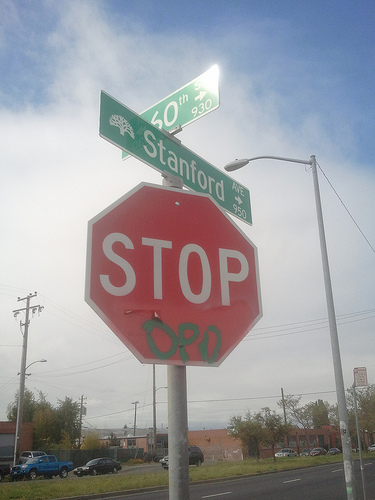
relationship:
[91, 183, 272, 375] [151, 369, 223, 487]
stop sign on pole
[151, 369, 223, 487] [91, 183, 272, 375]
pole holding stop sign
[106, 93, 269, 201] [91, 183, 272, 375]
sign above stop sign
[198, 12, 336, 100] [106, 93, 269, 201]
sky above sign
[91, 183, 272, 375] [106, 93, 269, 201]
stop sign below sign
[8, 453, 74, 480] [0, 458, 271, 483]
truck parked on street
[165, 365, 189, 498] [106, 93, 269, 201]
pole holding sign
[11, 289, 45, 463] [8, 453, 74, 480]
post next to truck